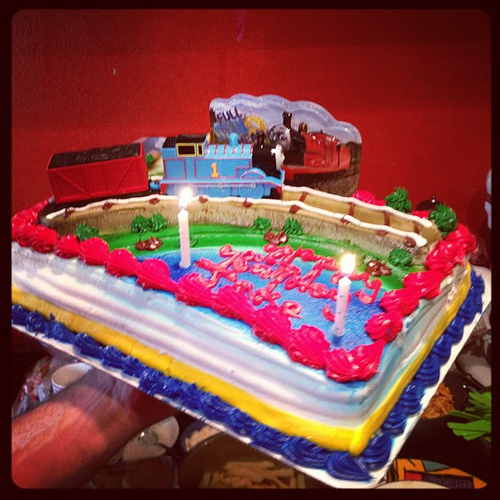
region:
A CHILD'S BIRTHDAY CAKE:
[14, 134, 485, 484]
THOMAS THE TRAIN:
[32, 128, 316, 235]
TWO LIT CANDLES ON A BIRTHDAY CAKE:
[168, 176, 376, 346]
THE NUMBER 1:
[191, 153, 241, 185]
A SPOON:
[127, 418, 198, 466]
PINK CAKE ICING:
[306, 215, 481, 392]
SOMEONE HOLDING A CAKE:
[15, 96, 487, 483]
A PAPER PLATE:
[362, 454, 489, 491]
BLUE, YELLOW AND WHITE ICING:
[251, 378, 458, 489]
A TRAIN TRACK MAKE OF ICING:
[45, 178, 457, 255]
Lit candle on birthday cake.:
[325, 247, 362, 344]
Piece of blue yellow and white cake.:
[241, 389, 416, 456]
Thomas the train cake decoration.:
[19, 88, 359, 200]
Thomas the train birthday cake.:
[24, 86, 478, 390]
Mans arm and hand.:
[8, 379, 169, 481]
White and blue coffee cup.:
[43, 359, 93, 396]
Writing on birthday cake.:
[188, 227, 339, 351]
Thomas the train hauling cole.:
[46, 136, 291, 207]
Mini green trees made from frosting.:
[371, 179, 477, 238]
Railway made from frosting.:
[273, 186, 441, 258]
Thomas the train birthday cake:
[21, 81, 498, 495]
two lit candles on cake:
[170, 140, 390, 360]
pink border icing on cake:
[15, 187, 460, 372]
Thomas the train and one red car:
[42, 125, 297, 208]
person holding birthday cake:
[16, 315, 231, 481]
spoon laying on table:
[127, 417, 195, 480]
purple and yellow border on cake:
[15, 280, 446, 483]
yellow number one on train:
[200, 150, 230, 188]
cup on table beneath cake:
[26, 353, 107, 428]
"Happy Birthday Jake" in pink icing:
[195, 212, 385, 362]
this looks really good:
[45, 83, 426, 355]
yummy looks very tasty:
[143, 218, 402, 415]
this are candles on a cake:
[162, 211, 383, 344]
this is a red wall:
[221, 30, 426, 103]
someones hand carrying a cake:
[32, 366, 179, 493]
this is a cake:
[90, 223, 496, 414]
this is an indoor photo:
[22, 211, 471, 473]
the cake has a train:
[41, 148, 370, 311]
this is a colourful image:
[51, 18, 485, 261]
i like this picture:
[71, 89, 346, 426]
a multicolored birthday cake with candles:
[14, 104, 494, 491]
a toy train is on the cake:
[43, 133, 296, 207]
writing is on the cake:
[203, 236, 379, 328]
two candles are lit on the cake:
[171, 182, 363, 339]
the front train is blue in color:
[160, 130, 290, 200]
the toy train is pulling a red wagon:
[44, 126, 286, 202]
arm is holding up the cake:
[3, 359, 193, 499]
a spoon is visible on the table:
[138, 428, 183, 463]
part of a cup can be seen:
[49, 359, 92, 403]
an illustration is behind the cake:
[208, 95, 363, 201]